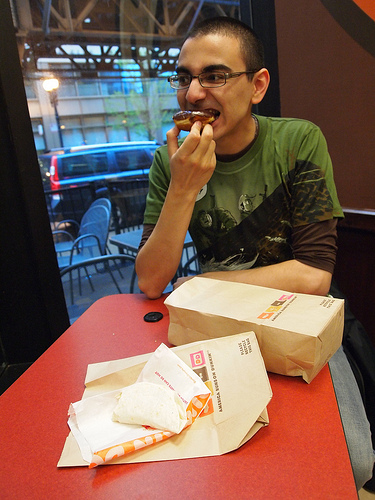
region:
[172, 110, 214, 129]
doughnut covered with chocolate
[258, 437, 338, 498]
red table top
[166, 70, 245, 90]
pair of silver eye glasses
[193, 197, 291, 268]
design on front of shirt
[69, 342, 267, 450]
brown paper bags on table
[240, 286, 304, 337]
design on paper bag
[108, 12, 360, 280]
man eating doughnut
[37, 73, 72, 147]
street light on black pole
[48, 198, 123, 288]
grey metal chairs on deck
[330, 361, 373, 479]
grey pants leg on man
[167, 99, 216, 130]
The donut is chocolate.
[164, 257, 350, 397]
the bag is brown.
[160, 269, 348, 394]
The bag is paper.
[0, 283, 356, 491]
The table is orange.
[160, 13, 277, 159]
Boy is eating a donut.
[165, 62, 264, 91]
The boy is wearing glasses.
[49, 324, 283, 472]
Napkins on the table.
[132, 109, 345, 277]
The boy's shirt is green.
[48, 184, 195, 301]
Chairs on the patio.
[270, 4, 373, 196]
The wall is brown.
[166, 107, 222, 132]
Chocolate glazed donut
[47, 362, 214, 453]
Duncan Dounts breakfast taco with bite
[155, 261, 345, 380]
Fluffed brown paper bag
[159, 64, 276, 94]
Black rimmed glasses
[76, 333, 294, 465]
Flat Duncan Donuts paper bag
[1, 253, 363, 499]
Red table with fast food above it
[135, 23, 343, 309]
Man eating chocolate donut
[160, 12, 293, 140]
Short hair cut on man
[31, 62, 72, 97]
Lit streetlamp through a window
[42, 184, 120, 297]
Restaurant patio furniture through window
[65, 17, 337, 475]
man eating doughnut at dunkin donuts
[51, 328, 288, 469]
paper bag and napkins on a table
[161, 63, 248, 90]
glasses on a man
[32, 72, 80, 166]
street light outside on a pole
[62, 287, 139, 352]
orange table in a dunkin donuts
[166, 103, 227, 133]
chocolate glazed doughnut man is eating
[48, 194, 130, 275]
chairs outside on sidewalk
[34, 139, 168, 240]
car parked outside on street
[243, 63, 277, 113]
left ear of a man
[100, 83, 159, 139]
tree outside of the window on sidewalk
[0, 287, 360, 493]
A red table.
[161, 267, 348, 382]
A brown paper bag.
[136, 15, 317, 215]
The man is eating a donut.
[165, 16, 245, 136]
The man is wearing glasses.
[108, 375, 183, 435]
A napkin.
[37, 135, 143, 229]
An SUV.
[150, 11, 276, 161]
The man's hair is cut very short.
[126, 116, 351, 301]
The man is wearing a t-shirt.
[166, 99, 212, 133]
The donut has chocolate on it.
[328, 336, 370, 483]
Jeans.